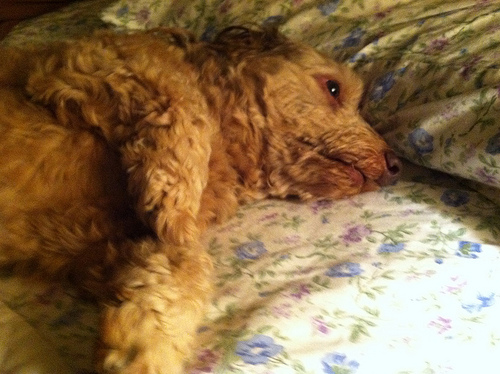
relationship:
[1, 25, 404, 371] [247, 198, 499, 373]
dog on bed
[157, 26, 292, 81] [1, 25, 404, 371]
fur of dog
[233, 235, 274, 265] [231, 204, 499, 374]
floral bed linen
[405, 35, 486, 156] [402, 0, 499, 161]
flowers on pillow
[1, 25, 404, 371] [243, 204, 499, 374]
dog on sheet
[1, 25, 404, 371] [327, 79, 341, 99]
dogs open eye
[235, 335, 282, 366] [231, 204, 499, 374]
flower on comforter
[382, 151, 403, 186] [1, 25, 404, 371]
nose of dog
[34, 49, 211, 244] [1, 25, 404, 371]
leg of dog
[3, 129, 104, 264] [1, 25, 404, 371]
belly on dog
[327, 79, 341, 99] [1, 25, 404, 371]
eye on dog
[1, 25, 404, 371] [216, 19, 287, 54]
dogs furry ear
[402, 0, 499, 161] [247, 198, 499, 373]
pillow on bed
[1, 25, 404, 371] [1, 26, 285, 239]
dogs brown fur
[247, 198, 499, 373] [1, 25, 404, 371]
bed under dog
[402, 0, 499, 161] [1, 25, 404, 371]
pillow under dog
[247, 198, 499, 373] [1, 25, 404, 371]
cot under dog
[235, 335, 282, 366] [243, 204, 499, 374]
flower on bedspread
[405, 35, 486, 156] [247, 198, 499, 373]
flowers on bed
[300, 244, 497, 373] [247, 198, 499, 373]
light on bed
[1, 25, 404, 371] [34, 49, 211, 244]
dogs folded leg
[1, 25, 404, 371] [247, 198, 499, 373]
dog under bed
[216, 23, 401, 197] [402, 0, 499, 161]
head on pillow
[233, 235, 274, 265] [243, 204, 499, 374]
floral bed sheet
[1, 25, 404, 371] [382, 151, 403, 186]
dogs brown nose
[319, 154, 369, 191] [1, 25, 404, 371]
mouth of dog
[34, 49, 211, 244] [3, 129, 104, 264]
leg on belly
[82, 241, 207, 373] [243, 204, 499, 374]
leg on sheet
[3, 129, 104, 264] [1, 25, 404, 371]
belly of dog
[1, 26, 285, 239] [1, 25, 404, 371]
fur on dog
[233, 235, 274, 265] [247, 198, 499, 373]
floral patterned bed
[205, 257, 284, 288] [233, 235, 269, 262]
leaves of floral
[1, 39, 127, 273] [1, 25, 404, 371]
side of dog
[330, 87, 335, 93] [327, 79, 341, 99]
dot on eye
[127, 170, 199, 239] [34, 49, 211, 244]
paw on leg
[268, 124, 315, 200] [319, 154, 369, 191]
fur around mouth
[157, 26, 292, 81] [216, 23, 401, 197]
fur on head